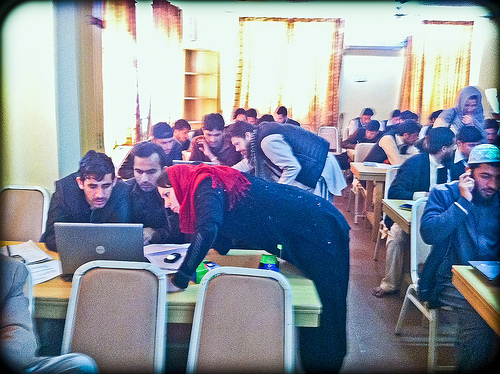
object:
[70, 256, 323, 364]
chairs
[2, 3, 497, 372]
classroom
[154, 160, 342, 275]
woman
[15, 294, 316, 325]
table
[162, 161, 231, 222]
scarf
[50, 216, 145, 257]
laptop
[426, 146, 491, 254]
man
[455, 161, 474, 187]
cell phone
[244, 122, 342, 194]
man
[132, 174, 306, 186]
table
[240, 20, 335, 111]
curtains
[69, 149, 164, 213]
men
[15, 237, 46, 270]
paperwork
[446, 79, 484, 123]
scarf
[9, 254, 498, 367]
front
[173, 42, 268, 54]
bookcase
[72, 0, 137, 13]
back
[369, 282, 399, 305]
foot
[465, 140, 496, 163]
hat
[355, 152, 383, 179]
table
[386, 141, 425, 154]
arms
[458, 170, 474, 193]
finger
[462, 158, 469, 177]
ear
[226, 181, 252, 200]
fringe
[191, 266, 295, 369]
chair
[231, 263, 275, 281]
metal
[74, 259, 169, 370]
chair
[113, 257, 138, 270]
metal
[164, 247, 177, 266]
cell phone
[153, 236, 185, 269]
papers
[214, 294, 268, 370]
seat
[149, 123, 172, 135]
hat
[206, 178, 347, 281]
dress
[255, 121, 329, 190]
vest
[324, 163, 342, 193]
hijab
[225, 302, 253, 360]
brown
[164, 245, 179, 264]
mouse